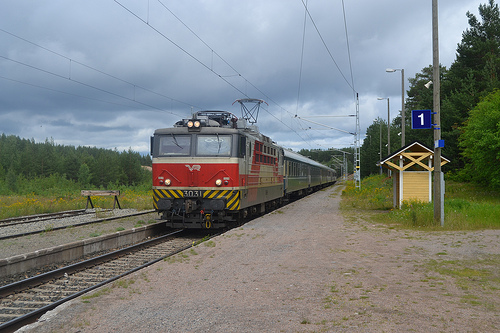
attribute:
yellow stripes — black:
[139, 187, 264, 222]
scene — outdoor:
[1, 0, 499, 331]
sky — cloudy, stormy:
[1, 3, 499, 148]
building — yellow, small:
[375, 142, 450, 207]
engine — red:
[147, 108, 287, 233]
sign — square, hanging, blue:
[407, 99, 429, 153]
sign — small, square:
[410, 107, 433, 124]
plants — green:
[457, 91, 496, 171]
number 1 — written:
[412, 107, 433, 132]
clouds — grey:
[196, 39, 328, 101]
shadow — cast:
[143, 218, 210, 242]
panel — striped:
[131, 182, 245, 230]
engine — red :
[149, 175, 238, 244]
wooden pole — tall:
[428, 5, 444, 226]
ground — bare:
[238, 221, 496, 328]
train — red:
[152, 116, 266, 238]